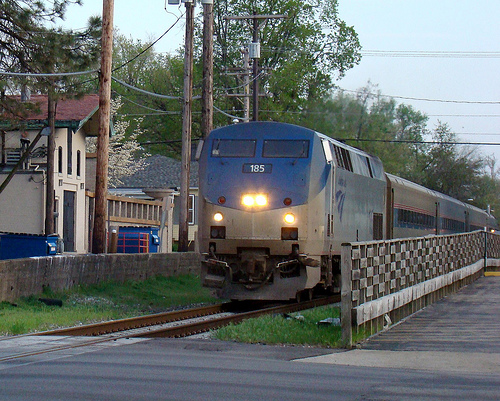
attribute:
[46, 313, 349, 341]
railwayline — part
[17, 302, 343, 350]
grass — green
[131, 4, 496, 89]
sky — blue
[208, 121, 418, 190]
train — moving, going, passing, passing house, by trees, silver, blue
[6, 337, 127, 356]
floor — part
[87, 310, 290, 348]
tracks — set